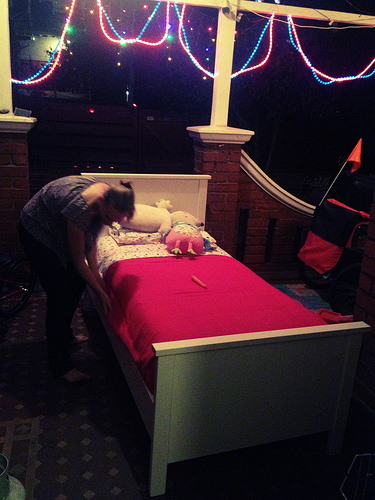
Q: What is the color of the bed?
A: White.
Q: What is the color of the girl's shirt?
A: Blue.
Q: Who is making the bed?
A: A girl.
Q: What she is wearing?
A: Shirt and pants.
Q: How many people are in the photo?
A: One.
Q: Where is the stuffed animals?
A: In the bed.